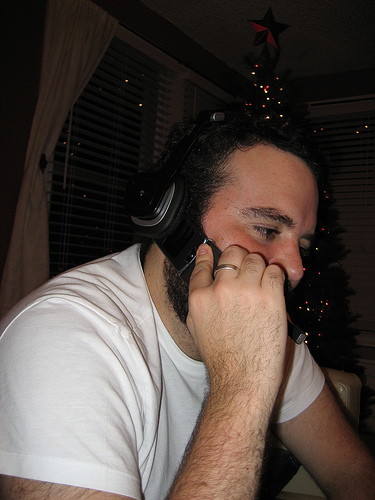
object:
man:
[0, 117, 375, 500]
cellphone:
[153, 213, 223, 291]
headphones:
[129, 111, 251, 242]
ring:
[214, 263, 240, 277]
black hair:
[164, 112, 308, 184]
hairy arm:
[163, 382, 276, 500]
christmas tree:
[244, 65, 356, 350]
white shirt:
[0, 242, 327, 500]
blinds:
[94, 81, 149, 145]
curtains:
[47, 0, 93, 86]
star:
[249, 7, 291, 51]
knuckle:
[186, 282, 282, 310]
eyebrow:
[240, 206, 297, 230]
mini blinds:
[337, 114, 375, 186]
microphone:
[287, 319, 307, 345]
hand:
[184, 243, 288, 395]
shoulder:
[0, 290, 136, 478]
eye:
[249, 222, 280, 240]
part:
[221, 245, 305, 310]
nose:
[268, 239, 304, 289]